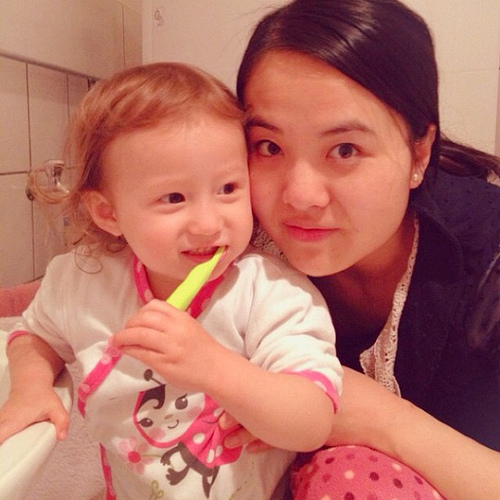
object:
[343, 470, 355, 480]
polka dot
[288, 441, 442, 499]
baby pants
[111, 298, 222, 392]
child's hand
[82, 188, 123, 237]
right ear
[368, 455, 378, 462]
polka dot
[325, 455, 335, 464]
polka dot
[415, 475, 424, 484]
polka dot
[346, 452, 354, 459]
polka dot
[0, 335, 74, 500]
bathtub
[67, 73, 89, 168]
tile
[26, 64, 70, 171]
tile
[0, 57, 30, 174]
tile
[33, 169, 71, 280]
tile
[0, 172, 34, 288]
tile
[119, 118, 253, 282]
face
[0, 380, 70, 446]
hand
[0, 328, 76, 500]
bathtub rim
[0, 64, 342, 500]
baby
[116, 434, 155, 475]
flower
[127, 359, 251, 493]
picture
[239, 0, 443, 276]
hair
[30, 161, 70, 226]
faucet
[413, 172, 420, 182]
pearl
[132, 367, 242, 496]
ladybug character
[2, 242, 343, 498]
clothing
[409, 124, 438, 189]
ear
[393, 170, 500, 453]
blazer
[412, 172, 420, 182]
earring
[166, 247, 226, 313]
brush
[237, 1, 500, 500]
lady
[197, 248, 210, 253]
baby teeth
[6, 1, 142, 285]
wall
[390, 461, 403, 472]
polka dots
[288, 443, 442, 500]
pants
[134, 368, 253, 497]
lady bug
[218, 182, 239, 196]
eye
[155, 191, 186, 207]
eye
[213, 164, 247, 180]
eyebrow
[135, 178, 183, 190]
eyebrow